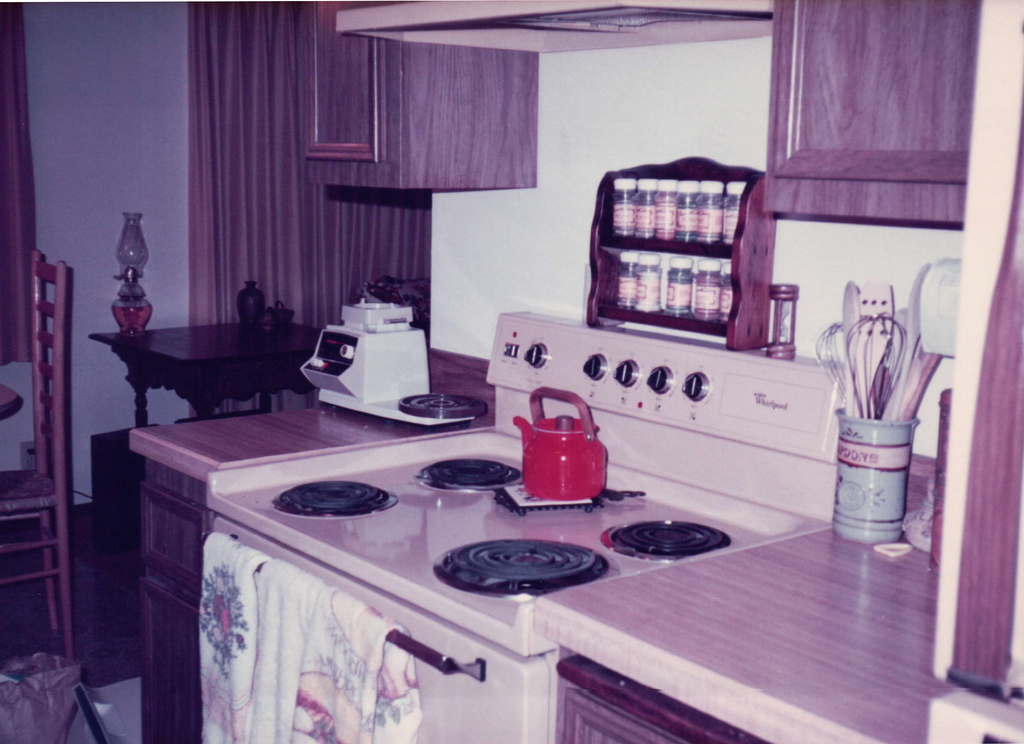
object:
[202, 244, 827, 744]
oven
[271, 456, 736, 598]
burners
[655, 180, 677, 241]
bottle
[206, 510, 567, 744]
oven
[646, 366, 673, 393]
oven knob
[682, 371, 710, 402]
oven knob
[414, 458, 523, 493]
burner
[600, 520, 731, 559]
burner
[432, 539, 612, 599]
burner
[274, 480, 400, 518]
burner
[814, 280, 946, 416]
utensils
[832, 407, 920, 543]
can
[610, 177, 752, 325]
spices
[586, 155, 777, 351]
rack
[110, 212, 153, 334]
lamp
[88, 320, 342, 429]
table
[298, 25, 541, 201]
cabinet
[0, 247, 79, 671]
chair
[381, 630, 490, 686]
handle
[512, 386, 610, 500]
kettle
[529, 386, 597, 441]
handle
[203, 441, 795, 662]
stove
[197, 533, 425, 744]
cloths